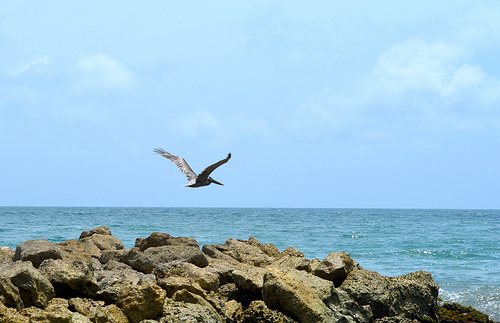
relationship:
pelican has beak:
[152, 145, 233, 193] [211, 177, 224, 187]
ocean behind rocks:
[1, 204, 499, 323] [260, 264, 334, 322]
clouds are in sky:
[290, 36, 499, 138] [1, 2, 500, 212]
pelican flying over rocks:
[152, 145, 233, 193] [260, 264, 334, 322]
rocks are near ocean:
[260, 264, 334, 322] [1, 204, 499, 323]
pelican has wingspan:
[152, 145, 233, 193] [150, 145, 233, 180]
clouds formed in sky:
[290, 36, 499, 138] [1, 2, 500, 212]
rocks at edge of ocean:
[260, 264, 334, 322] [1, 204, 499, 323]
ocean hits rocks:
[1, 204, 499, 323] [260, 264, 334, 322]